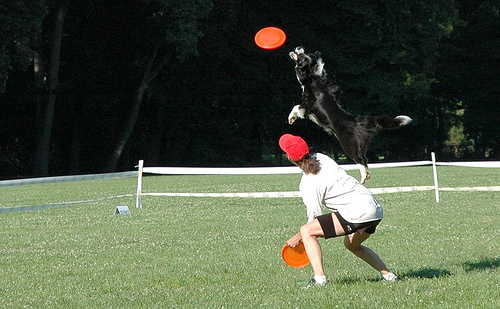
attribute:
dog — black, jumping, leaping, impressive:
[287, 45, 413, 186]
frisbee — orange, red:
[253, 26, 286, 50]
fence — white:
[3, 153, 498, 218]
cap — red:
[278, 133, 310, 160]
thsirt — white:
[297, 153, 383, 223]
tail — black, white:
[374, 113, 412, 131]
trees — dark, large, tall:
[1, 0, 498, 180]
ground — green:
[0, 162, 500, 308]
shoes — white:
[297, 271, 398, 291]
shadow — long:
[332, 266, 454, 287]